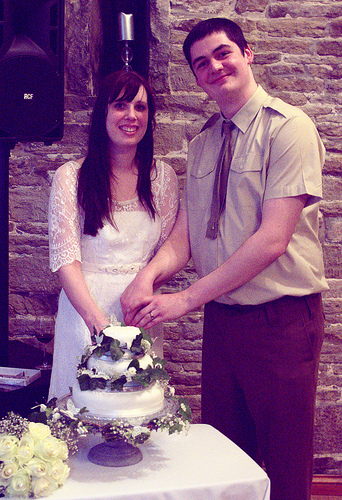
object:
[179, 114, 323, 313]
arm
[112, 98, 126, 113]
eyes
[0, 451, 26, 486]
rose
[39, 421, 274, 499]
table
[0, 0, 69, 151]
speaker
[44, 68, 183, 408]
woman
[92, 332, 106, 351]
flower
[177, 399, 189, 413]
flower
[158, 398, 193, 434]
flower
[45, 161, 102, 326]
arm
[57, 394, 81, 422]
butterflies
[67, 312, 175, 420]
cake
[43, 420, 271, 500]
tablecloth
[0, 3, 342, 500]
wall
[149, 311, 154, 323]
ring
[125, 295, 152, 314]
finger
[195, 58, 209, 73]
eyes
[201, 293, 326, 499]
pants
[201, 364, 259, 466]
leg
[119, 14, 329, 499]
guy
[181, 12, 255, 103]
head